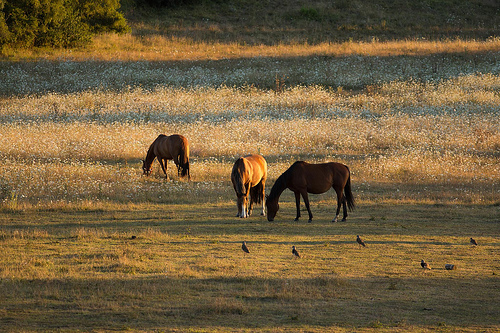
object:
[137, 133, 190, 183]
horse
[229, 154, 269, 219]
horse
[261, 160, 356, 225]
horse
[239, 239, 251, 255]
bird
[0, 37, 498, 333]
field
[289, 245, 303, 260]
bird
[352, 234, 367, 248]
bird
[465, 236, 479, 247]
bird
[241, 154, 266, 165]
back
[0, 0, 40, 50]
bushes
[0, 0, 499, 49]
background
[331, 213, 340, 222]
hoof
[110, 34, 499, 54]
area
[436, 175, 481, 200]
grass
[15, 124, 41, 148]
flowers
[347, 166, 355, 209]
tail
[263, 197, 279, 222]
horse's head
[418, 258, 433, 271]
bird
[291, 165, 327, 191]
horses' color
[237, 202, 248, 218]
face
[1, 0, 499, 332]
scene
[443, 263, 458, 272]
item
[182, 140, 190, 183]
tail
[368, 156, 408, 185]
grass